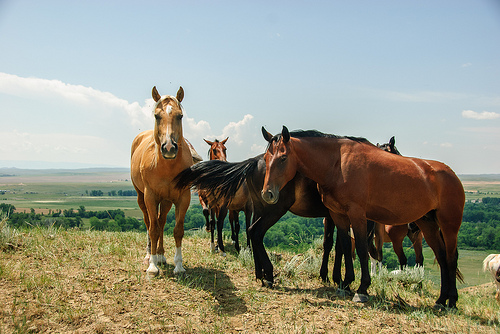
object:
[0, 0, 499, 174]
blue sky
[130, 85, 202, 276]
forelock horse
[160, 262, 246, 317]
shadow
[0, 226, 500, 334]
ground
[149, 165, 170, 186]
brown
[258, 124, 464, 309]
horse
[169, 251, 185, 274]
sock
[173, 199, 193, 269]
leg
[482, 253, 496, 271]
tail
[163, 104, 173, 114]
forelock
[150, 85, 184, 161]
head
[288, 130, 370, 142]
mane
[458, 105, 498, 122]
cloud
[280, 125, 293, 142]
ear